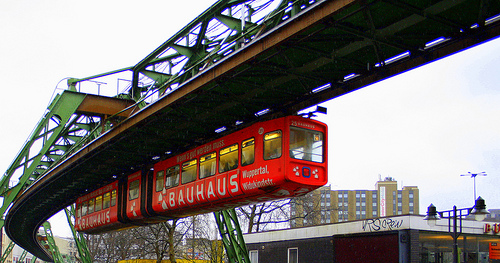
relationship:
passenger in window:
[194, 119, 310, 180] [229, 120, 287, 169]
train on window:
[62, 91, 341, 253] [229, 120, 287, 169]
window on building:
[245, 244, 256, 261] [226, 214, 497, 260]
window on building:
[285, 242, 299, 262] [226, 214, 497, 260]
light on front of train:
[311, 166, 320, 179] [62, 91, 341, 253]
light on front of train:
[290, 166, 299, 176] [62, 91, 341, 253]